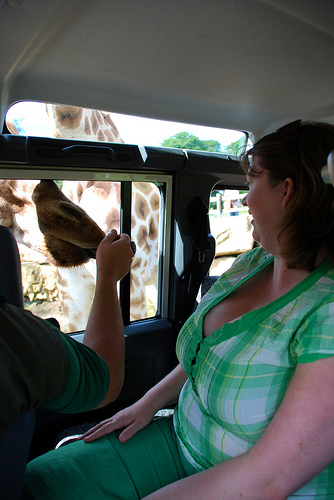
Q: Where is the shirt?
A: On the woman.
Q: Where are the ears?
A: On the woman.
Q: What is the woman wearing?
A: A green and white top.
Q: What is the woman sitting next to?
A: An open car window.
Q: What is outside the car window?
A: A giraffe.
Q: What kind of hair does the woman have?
A: Brown medium length.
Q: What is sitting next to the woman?
A: A person.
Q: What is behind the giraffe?
A: Trees.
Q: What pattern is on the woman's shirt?
A: Plaid.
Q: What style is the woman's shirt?
A: Short sleeved with a vee neck.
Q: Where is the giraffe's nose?
A: In the window.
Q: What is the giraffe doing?
A: Licking the person's hand.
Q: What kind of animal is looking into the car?
A: Giraffe.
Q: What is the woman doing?
A: Looking at the giraffe.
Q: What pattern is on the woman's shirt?
A: Plaid.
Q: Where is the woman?
A: In the car.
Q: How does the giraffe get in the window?
A: The window is down.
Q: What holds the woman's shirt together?
A: Buttons.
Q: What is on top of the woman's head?
A: Sunglasses.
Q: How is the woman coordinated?
A: Top and pants match.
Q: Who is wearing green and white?
A: A woman.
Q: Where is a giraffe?
A: Outside the vehicle.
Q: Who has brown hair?
A: The woman.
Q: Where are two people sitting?
A: In a vehicle.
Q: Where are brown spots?
A: On giraffe.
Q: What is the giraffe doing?
A: Eating from a hand.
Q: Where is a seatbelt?
A: Next to the window.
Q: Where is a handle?
A: Above the window.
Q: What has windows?
A: The vehicle.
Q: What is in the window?
A: Giraffe.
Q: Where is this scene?
A: Zoo.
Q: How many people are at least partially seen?
A: Two.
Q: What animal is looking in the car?
A: Giraffe.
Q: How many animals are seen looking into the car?
A: One.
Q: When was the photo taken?
A: Daytime.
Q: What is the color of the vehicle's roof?
A: White.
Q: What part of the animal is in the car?
A: Mouth.